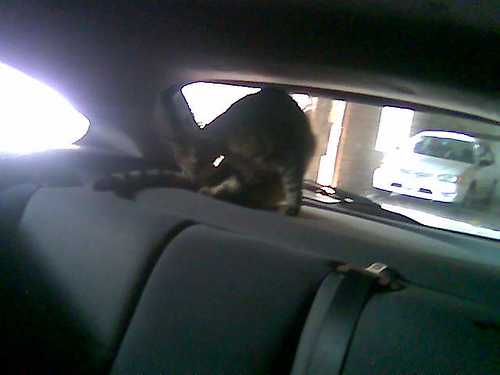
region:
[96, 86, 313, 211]
a cat is on the car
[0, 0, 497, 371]
the photo is blurry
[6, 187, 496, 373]
the seats are black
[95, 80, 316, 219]
the cat has stripes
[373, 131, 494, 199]
the car is white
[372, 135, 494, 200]
the car is parked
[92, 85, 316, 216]
the cat licks itself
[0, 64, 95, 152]
the light is bright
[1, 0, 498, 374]
the car is dark inside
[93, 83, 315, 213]
the cat sits in the back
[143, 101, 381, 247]
a cat on top of the back seat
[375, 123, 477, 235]
a white car in the background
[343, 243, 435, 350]
a seat belt on the back seat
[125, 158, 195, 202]
the tail of the cat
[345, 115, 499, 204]
an open garage in the back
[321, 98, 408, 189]
a brick wall near the garage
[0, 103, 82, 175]
sun shining through the window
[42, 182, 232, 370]
the back seat of the car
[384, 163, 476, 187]
the headlights of the car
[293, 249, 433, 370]
the seatbelt ready to be used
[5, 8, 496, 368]
Interior shot of vehicle with natural light.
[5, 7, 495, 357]
View of inside of car, showing windows and domesticated animal.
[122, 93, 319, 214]
Long-tailed cat, washing itself.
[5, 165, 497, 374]
Backseat of car, showing three sections and seat belt.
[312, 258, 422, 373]
Blue seat strap with metal buckle, matching blue seats.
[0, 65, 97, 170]
Strong sun glare, entering side window.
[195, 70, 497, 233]
Back window, visible behind cat.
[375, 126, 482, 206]
White car, visible through car window.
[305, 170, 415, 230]
Black windshield wiper, partially obstructed by washing cat.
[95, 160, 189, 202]
Striped cat-tail, with shadow, touching seat.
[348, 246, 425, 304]
a seat belt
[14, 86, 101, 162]
sun shining through the window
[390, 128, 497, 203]
a white car parked in the back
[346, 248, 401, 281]
a seatbelt on the back seat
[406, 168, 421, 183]
the brand of the car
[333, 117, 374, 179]
a part of the brick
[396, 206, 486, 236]
the ground behind the car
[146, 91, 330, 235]
the cat is in the car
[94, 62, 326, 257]
the cat is cleaning itself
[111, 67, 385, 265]
the cat is stripes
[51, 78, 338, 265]
the cat has a tail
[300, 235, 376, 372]
the seat belt is black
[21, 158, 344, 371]
car seat is gray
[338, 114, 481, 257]
the car is parked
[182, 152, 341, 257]
the cat has paws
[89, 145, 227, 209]
cat's tail is long